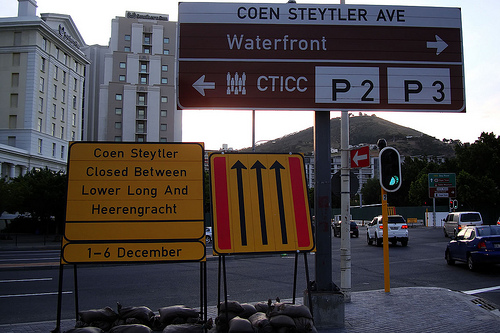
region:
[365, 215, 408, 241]
the truck is white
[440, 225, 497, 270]
the car is blue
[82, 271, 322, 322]
the sacks are brown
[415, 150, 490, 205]
the trees are green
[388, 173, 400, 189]
the traffic light is green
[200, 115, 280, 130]
the sky is cloudy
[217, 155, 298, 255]
the arrows are black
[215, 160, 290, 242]
the arrows are facing upwards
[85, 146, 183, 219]
the writing is black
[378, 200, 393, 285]
the pole is yellow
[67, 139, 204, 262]
a yellow sign is on the street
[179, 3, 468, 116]
direction sign is the corner street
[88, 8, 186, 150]
the building in the back is tall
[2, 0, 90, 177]
the building is white in color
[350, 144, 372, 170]
the sign is color red and white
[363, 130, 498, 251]
trees are in the background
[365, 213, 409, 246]
a white car is moving away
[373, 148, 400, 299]
the pole is painted yellow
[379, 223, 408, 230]
the brake light is red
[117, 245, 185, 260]
Yellow sign saying December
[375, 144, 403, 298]
Green traffic light signal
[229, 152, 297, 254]
three arrows pointing upward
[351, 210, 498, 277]
cars driving down the street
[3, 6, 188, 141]
tall tan-colored buildings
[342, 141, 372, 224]
red and white arrow sign on a metal post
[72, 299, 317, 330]
pile of sandbags holding signs down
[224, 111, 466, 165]
mountain in the background of the city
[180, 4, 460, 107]
brown and white street sign for Coen Steytler Ave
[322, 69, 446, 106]
black and white signs for P2 and P3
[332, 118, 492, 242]
Traffic light at the intersection.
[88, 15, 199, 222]
Building near intersection.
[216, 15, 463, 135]
Sign to the waterfront.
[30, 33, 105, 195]
Windows in the building.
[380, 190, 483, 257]
Cars in the intersection.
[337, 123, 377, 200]
Arrow on sign.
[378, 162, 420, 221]
Green light on traffic light.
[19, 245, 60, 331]
White lines painted on the asphalt.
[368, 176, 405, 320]
Yellow post with a traffic light on it.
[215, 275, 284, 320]
Sandbag holding signs.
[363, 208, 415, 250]
vehicle on a street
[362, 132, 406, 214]
traffic signal on a pole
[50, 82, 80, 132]
windows on a building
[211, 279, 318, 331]
sandbags on the bottom of a sign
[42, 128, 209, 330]
yellow sign adjacent a street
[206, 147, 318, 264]
three black arrows on a sign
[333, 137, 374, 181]
red sign with a white arrow on a pole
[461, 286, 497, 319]
drainage grate on a street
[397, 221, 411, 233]
rear tail light on a vehicle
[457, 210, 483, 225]
rear window of a vehicle